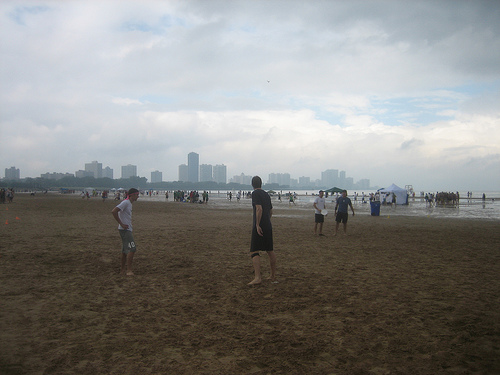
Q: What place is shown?
A: It is a beach.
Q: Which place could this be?
A: It is a beach.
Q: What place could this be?
A: It is a beach.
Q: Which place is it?
A: It is a beach.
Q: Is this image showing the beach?
A: Yes, it is showing the beach.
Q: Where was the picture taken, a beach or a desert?
A: It was taken at a beach.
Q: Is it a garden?
A: No, it is a beach.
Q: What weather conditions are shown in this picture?
A: It is cloudy.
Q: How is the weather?
A: It is cloudy.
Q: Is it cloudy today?
A: Yes, it is cloudy.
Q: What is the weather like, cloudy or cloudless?
A: It is cloudy.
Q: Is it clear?
A: No, it is cloudy.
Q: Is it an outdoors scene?
A: Yes, it is outdoors.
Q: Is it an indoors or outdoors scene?
A: It is outdoors.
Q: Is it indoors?
A: No, it is outdoors.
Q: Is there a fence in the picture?
A: No, there are no fences.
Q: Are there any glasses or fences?
A: No, there are no fences or glasses.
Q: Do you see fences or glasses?
A: No, there are no fences or glasses.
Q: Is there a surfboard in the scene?
A: No, there are no surfboards.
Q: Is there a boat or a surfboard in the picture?
A: No, there are no surfboards or boats.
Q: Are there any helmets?
A: No, there are no helmets.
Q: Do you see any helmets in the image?
A: No, there are no helmets.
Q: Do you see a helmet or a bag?
A: No, there are no helmets or bags.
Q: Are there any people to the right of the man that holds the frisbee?
A: Yes, there is a person to the right of the man.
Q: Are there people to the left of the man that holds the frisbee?
A: No, the person is to the right of the man.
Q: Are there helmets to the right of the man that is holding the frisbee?
A: No, there is a person to the right of the man.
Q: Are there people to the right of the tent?
A: No, the person is to the left of the tent.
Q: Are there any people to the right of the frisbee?
A: Yes, there is a person to the right of the frisbee.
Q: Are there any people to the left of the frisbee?
A: No, the person is to the right of the frisbee.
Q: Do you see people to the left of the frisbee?
A: No, the person is to the right of the frisbee.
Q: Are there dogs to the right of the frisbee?
A: No, there is a person to the right of the frisbee.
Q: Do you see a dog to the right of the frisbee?
A: No, there is a person to the right of the frisbee.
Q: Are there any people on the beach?
A: Yes, there is a person on the beach.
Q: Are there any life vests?
A: No, there are no life vests.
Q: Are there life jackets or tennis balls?
A: No, there are no life jackets or tennis balls.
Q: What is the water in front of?
A: The water is in front of the building.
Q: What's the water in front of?
A: The water is in front of the building.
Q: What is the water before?
A: The water is in front of the building.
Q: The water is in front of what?
A: The water is in front of the building.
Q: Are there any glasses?
A: No, there are no glasses.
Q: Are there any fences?
A: No, there are no fences.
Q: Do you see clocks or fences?
A: No, there are no fences or clocks.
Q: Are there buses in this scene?
A: No, there are no buses.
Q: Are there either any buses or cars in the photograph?
A: No, there are no buses or cars.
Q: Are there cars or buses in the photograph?
A: No, there are no buses or cars.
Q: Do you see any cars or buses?
A: No, there are no buses or cars.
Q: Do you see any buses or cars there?
A: No, there are no buses or cars.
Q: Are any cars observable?
A: No, there are no cars.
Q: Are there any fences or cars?
A: No, there are no cars or fences.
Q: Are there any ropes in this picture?
A: No, there are no ropes.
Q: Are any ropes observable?
A: No, there are no ropes.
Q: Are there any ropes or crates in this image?
A: No, there are no ropes or crates.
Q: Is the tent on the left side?
A: No, the tent is on the right of the image.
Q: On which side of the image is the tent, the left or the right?
A: The tent is on the right of the image.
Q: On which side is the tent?
A: The tent is on the right of the image.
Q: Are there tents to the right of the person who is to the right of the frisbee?
A: Yes, there is a tent to the right of the person.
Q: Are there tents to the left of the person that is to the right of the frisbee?
A: No, the tent is to the right of the person.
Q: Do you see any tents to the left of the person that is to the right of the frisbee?
A: No, the tent is to the right of the person.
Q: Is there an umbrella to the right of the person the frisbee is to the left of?
A: No, there is a tent to the right of the person.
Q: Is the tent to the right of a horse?
A: No, the tent is to the right of a person.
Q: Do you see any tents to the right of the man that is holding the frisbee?
A: Yes, there is a tent to the right of the man.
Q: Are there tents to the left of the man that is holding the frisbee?
A: No, the tent is to the right of the man.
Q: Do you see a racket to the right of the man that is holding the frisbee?
A: No, there is a tent to the right of the man.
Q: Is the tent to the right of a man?
A: Yes, the tent is to the right of a man.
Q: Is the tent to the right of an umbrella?
A: No, the tent is to the right of a man.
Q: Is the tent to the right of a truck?
A: No, the tent is to the right of a man.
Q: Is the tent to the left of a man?
A: No, the tent is to the right of a man.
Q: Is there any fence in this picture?
A: No, there are no fences.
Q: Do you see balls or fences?
A: No, there are no fences or balls.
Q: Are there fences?
A: No, there are no fences.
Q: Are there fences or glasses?
A: No, there are no fences or glasses.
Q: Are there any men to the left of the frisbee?
A: Yes, there is a man to the left of the frisbee.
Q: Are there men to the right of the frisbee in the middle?
A: No, the man is to the left of the frisbee.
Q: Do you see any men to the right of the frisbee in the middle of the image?
A: No, the man is to the left of the frisbee.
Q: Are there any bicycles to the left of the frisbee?
A: No, there is a man to the left of the frisbee.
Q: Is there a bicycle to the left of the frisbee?
A: No, there is a man to the left of the frisbee.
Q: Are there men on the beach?
A: Yes, there is a man on the beach.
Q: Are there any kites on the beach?
A: No, there is a man on the beach.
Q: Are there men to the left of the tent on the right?
A: Yes, there is a man to the left of the tent.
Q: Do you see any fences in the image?
A: No, there are no fences.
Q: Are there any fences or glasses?
A: No, there are no fences or glasses.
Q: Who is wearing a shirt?
A: The man is wearing a shirt.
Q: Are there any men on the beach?
A: Yes, there is a man on the beach.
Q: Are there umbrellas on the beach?
A: No, there is a man on the beach.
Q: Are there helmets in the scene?
A: No, there are no helmets.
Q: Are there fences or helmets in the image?
A: No, there are no helmets or fences.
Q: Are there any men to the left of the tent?
A: Yes, there is a man to the left of the tent.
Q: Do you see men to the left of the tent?
A: Yes, there is a man to the left of the tent.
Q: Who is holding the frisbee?
A: The man is holding the frisbee.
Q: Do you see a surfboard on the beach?
A: No, there is a man on the beach.